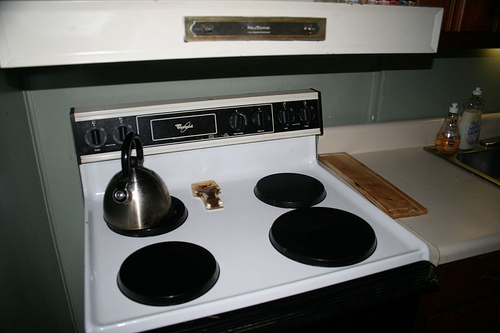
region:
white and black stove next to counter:
[60, 86, 430, 326]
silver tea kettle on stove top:
[100, 131, 165, 226]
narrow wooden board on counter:
[316, 150, 423, 220]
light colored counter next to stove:
[312, 107, 494, 267]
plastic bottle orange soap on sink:
[432, 100, 457, 150]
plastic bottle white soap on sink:
[455, 85, 480, 150]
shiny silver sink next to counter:
[425, 132, 495, 192]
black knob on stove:
[80, 122, 102, 147]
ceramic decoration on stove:
[190, 175, 225, 206]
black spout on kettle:
[107, 185, 125, 205]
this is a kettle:
[102, 131, 183, 232]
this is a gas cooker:
[76, 130, 418, 330]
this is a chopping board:
[320, 150, 430, 221]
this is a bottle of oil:
[420, 100, 463, 163]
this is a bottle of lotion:
[458, 80, 488, 160]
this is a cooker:
[266, 195, 376, 267]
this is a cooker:
[245, 165, 333, 205]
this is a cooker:
[112, 238, 232, 303]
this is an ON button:
[80, 126, 110, 146]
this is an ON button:
[116, 123, 138, 146]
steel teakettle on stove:
[82, 141, 174, 251]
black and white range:
[75, 96, 375, 296]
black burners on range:
[72, 163, 352, 275]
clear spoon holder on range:
[189, 178, 247, 225]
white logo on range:
[165, 115, 202, 138]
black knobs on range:
[63, 107, 141, 144]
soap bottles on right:
[435, 82, 497, 167]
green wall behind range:
[257, 72, 393, 110]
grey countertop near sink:
[366, 127, 481, 251]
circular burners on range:
[250, 208, 352, 263]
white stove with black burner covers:
[66, 88, 430, 331]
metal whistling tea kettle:
[100, 132, 172, 234]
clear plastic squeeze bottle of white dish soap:
[460, 83, 485, 148]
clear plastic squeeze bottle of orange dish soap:
[433, 99, 458, 151]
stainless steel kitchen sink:
[423, 137, 498, 186]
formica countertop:
[320, 152, 498, 263]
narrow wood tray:
[314, 150, 428, 220]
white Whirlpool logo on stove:
[172, 120, 197, 131]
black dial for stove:
[83, 125, 108, 149]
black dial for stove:
[226, 110, 249, 134]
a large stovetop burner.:
[265, 201, 400, 271]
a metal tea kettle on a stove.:
[100, 127, 187, 245]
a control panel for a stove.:
[54, 83, 329, 178]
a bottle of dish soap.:
[435, 96, 460, 151]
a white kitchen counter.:
[317, 120, 498, 273]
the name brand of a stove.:
[141, 105, 218, 152]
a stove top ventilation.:
[1, 1, 448, 59]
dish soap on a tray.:
[464, 76, 484, 161]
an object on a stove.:
[189, 169, 239, 219]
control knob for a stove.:
[106, 110, 138, 156]